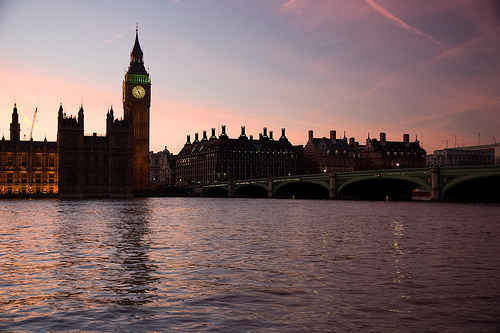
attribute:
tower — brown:
[125, 25, 157, 190]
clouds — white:
[305, 4, 491, 119]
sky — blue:
[152, 9, 499, 96]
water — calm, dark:
[5, 199, 500, 331]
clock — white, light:
[128, 82, 147, 102]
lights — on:
[214, 168, 417, 176]